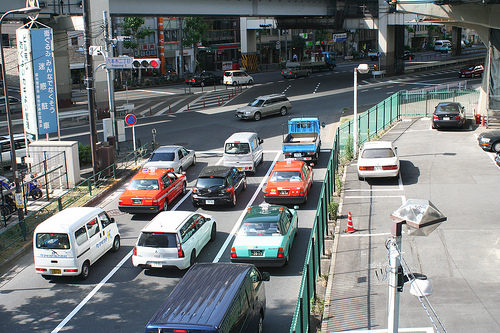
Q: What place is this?
A: It is a road.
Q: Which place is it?
A: It is a road.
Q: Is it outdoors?
A: Yes, it is outdoors.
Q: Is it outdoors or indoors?
A: It is outdoors.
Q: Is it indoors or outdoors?
A: It is outdoors.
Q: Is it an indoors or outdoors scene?
A: It is outdoors.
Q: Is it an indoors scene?
A: No, it is outdoors.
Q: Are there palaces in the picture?
A: No, there are no palaces.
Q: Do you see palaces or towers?
A: No, there are no palaces or towers.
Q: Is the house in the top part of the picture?
A: No, the house is in the bottom of the image.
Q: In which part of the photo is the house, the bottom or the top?
A: The house is in the bottom of the image.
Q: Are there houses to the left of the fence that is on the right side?
A: Yes, there is a house to the left of the fence.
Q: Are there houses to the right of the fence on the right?
A: No, the house is to the left of the fence.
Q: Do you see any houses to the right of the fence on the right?
A: No, the house is to the left of the fence.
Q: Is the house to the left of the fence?
A: Yes, the house is to the left of the fence.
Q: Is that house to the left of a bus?
A: No, the house is to the left of the fence.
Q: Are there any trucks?
A: Yes, there is a truck.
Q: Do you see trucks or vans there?
A: Yes, there is a truck.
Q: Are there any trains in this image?
A: No, there are no trains.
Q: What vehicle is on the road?
A: The vehicle is a truck.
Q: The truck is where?
A: The truck is on the road.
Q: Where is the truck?
A: The truck is on the road.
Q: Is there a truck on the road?
A: Yes, there is a truck on the road.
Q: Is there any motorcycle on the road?
A: No, there is a truck on the road.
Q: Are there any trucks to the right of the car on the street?
A: No, the truck is to the left of the car.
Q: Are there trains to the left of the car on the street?
A: No, there is a truck to the left of the car.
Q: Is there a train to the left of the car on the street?
A: No, there is a truck to the left of the car.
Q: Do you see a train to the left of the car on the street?
A: No, there is a truck to the left of the car.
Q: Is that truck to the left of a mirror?
A: No, the truck is to the left of a car.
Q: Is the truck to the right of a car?
A: Yes, the truck is to the right of a car.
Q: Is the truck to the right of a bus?
A: No, the truck is to the right of a car.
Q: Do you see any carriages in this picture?
A: No, there are no carriages.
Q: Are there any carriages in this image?
A: No, there are no carriages.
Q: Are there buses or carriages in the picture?
A: No, there are no carriages or buses.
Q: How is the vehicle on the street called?
A: The vehicle is a car.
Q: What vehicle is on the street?
A: The vehicle is a car.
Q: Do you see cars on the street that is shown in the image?
A: Yes, there is a car on the street.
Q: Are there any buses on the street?
A: No, there is a car on the street.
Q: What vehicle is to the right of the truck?
A: The vehicle is a car.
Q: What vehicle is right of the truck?
A: The vehicle is a car.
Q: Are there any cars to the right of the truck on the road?
A: Yes, there is a car to the right of the truck.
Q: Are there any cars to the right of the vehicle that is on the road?
A: Yes, there is a car to the right of the truck.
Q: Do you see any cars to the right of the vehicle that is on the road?
A: Yes, there is a car to the right of the truck.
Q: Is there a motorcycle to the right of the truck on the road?
A: No, there is a car to the right of the truck.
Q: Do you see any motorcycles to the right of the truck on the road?
A: No, there is a car to the right of the truck.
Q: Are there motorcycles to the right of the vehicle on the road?
A: No, there is a car to the right of the truck.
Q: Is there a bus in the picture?
A: No, there are no buses.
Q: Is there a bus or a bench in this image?
A: No, there are no buses or benches.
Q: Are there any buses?
A: No, there are no buses.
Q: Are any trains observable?
A: No, there are no trains.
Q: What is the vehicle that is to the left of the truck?
A: The vehicle is a car.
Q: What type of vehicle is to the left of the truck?
A: The vehicle is a car.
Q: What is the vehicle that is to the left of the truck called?
A: The vehicle is a car.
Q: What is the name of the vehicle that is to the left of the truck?
A: The vehicle is a car.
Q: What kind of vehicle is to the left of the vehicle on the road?
A: The vehicle is a car.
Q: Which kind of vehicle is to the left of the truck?
A: The vehicle is a car.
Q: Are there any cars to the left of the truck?
A: Yes, there is a car to the left of the truck.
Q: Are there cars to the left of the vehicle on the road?
A: Yes, there is a car to the left of the truck.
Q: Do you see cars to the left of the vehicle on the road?
A: Yes, there is a car to the left of the truck.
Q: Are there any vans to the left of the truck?
A: No, there is a car to the left of the truck.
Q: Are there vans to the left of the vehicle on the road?
A: No, there is a car to the left of the truck.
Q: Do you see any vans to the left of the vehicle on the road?
A: No, there is a car to the left of the truck.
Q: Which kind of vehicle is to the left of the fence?
A: The vehicle is a car.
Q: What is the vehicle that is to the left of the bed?
A: The vehicle is a car.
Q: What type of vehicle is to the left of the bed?
A: The vehicle is a car.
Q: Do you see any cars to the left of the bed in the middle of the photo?
A: Yes, there is a car to the left of the bed.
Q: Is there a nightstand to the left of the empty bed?
A: No, there is a car to the left of the bed.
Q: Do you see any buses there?
A: No, there are no buses.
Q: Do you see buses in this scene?
A: No, there are no buses.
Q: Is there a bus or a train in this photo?
A: No, there are no buses or trains.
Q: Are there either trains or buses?
A: No, there are no buses or trains.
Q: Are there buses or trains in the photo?
A: No, there are no buses or trains.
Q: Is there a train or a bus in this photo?
A: No, there are no buses or trains.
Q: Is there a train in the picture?
A: No, there are no trains.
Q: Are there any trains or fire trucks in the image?
A: No, there are no trains or fire trucks.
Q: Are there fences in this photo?
A: Yes, there is a fence.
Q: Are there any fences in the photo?
A: Yes, there is a fence.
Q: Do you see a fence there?
A: Yes, there is a fence.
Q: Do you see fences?
A: Yes, there is a fence.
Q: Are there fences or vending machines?
A: Yes, there is a fence.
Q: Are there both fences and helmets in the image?
A: No, there is a fence but no helmets.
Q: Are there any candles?
A: No, there are no candles.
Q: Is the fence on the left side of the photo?
A: No, the fence is on the right of the image.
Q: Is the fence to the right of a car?
A: Yes, the fence is to the right of a car.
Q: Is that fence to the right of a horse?
A: No, the fence is to the right of a car.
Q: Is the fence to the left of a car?
A: No, the fence is to the right of a car.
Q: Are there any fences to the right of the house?
A: Yes, there is a fence to the right of the house.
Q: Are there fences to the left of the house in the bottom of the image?
A: No, the fence is to the right of the house.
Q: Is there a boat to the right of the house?
A: No, there is a fence to the right of the house.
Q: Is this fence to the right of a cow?
A: No, the fence is to the right of the house.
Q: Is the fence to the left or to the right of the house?
A: The fence is to the right of the house.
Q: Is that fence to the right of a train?
A: No, the fence is to the right of a car.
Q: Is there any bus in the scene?
A: No, there are no buses.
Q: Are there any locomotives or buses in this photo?
A: No, there are no buses or locomotives.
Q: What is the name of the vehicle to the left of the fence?
A: The vehicle is a car.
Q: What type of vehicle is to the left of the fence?
A: The vehicle is a car.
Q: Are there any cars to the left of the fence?
A: Yes, there is a car to the left of the fence.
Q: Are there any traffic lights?
A: Yes, there is a traffic light.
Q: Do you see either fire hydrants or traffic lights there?
A: Yes, there is a traffic light.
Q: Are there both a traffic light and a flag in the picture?
A: No, there is a traffic light but no flags.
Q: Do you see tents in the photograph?
A: No, there are no tents.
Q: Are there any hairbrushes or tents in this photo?
A: No, there are no tents or hairbrushes.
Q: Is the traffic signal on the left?
A: Yes, the traffic signal is on the left of the image.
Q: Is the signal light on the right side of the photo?
A: No, the signal light is on the left of the image.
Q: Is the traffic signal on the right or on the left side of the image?
A: The traffic signal is on the left of the image.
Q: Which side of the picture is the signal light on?
A: The signal light is on the left of the image.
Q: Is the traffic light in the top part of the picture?
A: Yes, the traffic light is in the top of the image.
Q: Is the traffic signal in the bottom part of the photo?
A: No, the traffic signal is in the top of the image.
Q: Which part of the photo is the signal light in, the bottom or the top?
A: The signal light is in the top of the image.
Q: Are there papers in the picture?
A: No, there are no papers.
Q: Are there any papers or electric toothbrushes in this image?
A: No, there are no papers or electric toothbrushes.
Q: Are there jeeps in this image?
A: No, there are no jeeps.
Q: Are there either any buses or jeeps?
A: No, there are no jeeps or buses.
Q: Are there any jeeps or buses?
A: No, there are no jeeps or buses.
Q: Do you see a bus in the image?
A: No, there are no buses.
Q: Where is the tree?
A: The tree is on the road.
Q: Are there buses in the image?
A: No, there are no buses.